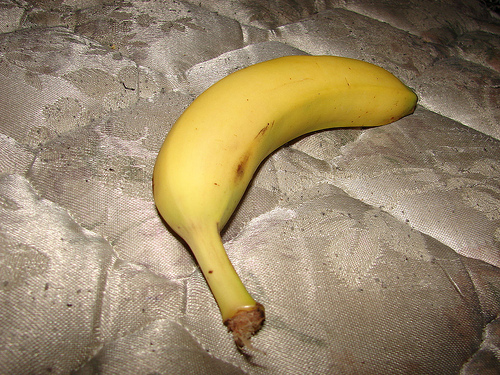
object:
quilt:
[0, 0, 500, 375]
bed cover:
[279, 131, 415, 276]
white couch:
[229, 126, 499, 269]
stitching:
[106, 312, 222, 371]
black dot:
[208, 270, 213, 273]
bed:
[0, 0, 500, 375]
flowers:
[66, 11, 151, 60]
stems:
[0, 0, 152, 91]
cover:
[0, 0, 500, 375]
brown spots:
[232, 147, 253, 183]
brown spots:
[254, 120, 276, 139]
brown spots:
[390, 116, 394, 120]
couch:
[9, 0, 500, 375]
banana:
[151, 55, 418, 354]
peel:
[152, 55, 417, 325]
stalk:
[188, 243, 266, 355]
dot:
[208, 270, 213, 273]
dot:
[214, 182, 217, 185]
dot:
[233, 150, 253, 182]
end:
[209, 285, 265, 353]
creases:
[309, 162, 482, 318]